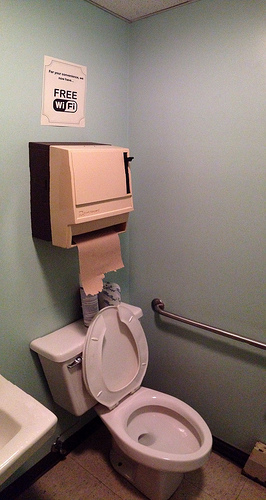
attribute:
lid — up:
[97, 311, 148, 376]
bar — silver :
[159, 288, 260, 360]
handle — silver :
[61, 356, 87, 371]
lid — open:
[85, 300, 150, 407]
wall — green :
[129, 18, 260, 293]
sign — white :
[40, 53, 88, 129]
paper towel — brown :
[73, 228, 125, 297]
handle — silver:
[138, 296, 246, 334]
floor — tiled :
[32, 458, 115, 496]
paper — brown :
[77, 229, 125, 284]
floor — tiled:
[12, 419, 265, 499]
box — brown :
[239, 440, 264, 485]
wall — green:
[134, 0, 264, 468]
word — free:
[49, 77, 92, 108]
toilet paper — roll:
[98, 279, 127, 314]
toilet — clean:
[28, 294, 209, 492]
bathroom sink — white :
[0, 369, 67, 490]